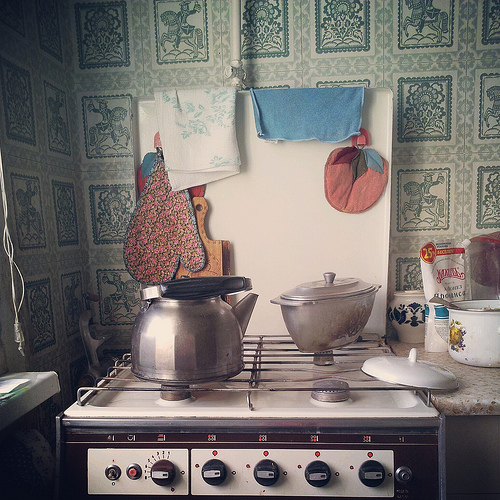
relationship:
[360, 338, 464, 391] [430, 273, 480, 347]
top to pot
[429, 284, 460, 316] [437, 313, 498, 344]
utensil sticking out of pot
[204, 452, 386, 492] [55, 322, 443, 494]
knobs on an oven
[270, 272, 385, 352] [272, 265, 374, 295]
container with lid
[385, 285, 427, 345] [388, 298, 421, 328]
tin with pattern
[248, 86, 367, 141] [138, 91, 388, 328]
blue towel on board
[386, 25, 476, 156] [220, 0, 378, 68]
wallpaper with pattern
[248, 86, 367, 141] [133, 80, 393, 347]
blue towel draped over wall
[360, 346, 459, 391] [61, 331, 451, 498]
top on stove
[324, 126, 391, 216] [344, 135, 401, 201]
holder with designs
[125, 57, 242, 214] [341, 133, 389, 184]
towel with designs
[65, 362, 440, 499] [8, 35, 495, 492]
oven in kitchen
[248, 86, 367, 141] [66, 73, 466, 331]
blue towel on wall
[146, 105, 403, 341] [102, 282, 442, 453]
board behind oven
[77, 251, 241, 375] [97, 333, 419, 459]
lid on stove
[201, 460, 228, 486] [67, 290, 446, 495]
knob of oven